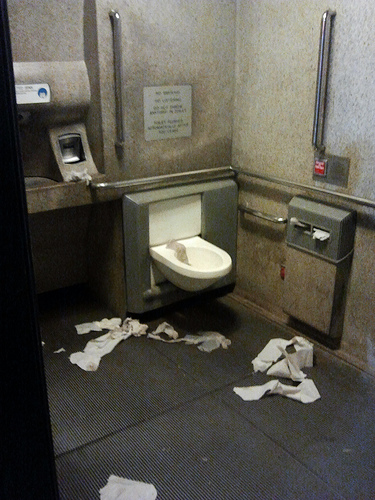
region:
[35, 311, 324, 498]
white toilet paper on the floor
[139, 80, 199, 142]
sign above the toilet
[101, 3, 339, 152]
two vertical silver support rails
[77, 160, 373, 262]
two horizontal silver support rails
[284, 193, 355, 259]
gray toilet paper dispenser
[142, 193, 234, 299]
white toilet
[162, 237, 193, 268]
wet toilet paper on a white toilet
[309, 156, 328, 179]
red assistance button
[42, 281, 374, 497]
black grooved floor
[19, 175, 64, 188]
white sink basin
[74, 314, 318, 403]
Toilet paper on the floor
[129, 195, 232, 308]
Toilet is white and grey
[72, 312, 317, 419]
Toilet paper is white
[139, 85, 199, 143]
White sign above the toilet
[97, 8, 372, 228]
Silver bars around toilet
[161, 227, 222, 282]
Toilet paper in the toilet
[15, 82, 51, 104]
White and blue sign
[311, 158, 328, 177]
Red and white square sign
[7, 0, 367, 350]
The wall is tan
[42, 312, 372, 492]
The floor is grey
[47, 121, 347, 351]
THIS IS A PUBLIC RESTROOM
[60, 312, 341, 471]
TOILET PAPER LITTERS THE FLOOR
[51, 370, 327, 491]
FLOOR IS DARK GRAY AND DINGY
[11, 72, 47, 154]
AIR DRYER FOR HANDS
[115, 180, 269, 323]
COMMODE IS ATTACHED TO WALL AREA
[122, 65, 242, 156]
SIGN ON RESTROOM WALL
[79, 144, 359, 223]
HAND BARS ON WALL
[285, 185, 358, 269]
TOILET PAPER DISPENSER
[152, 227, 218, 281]
WET TOILET PAPER LEFT IN BOWL OF COMMODE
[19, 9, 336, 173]
WALLS ARE BEIGE IN COLOR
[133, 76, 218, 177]
A sign is on the wall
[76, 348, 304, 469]
Trash is on the floor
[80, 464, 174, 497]
A piece of paper is on the floor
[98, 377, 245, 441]
The floor is gray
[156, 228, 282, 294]
A toilet is white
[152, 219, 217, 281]
Tissue is on the toilet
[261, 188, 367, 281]
A toilet paper dispenser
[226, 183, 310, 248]
A bar is next to the toilet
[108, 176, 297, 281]
A toilet is connected to the wall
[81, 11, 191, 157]
A pole is above the toilet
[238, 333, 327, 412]
the toilet paper is on the floor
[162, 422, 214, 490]
the floor is black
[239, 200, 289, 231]
the handrail is shiney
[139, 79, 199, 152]
the plaque is on the wall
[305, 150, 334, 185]
the button is red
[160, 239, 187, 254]
the toilet paper is wet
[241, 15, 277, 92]
the wall is gray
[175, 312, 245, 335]
the shadow is on the floor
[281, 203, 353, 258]
the tissue is coming out of the box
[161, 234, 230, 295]
the bowl is white